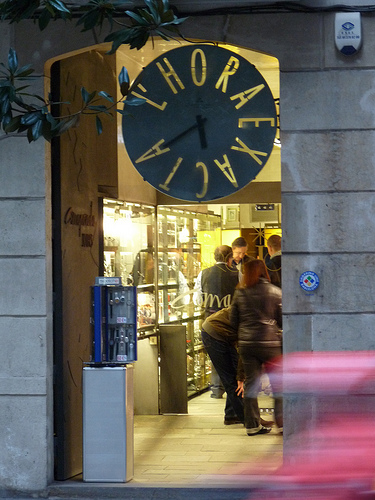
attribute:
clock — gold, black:
[120, 42, 276, 201]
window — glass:
[47, 52, 268, 481]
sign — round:
[122, 40, 280, 202]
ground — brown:
[133, 412, 296, 481]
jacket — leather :
[229, 280, 282, 346]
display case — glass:
[104, 200, 220, 403]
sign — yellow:
[114, 44, 272, 209]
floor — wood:
[137, 416, 233, 464]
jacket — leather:
[227, 277, 284, 346]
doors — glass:
[135, 215, 271, 331]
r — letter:
[212, 57, 245, 93]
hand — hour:
[161, 116, 211, 147]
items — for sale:
[127, 223, 210, 325]